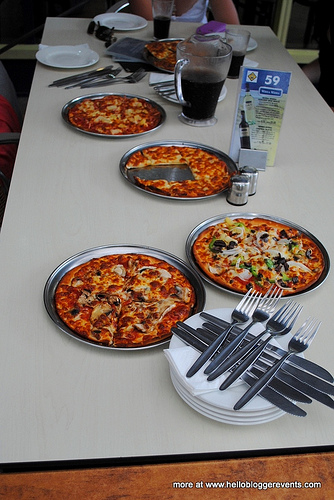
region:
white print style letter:
[172, 480, 179, 490]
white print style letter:
[179, 480, 185, 489]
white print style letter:
[185, 479, 187, 489]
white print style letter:
[187, 479, 193, 488]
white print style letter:
[194, 480, 199, 488]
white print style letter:
[199, 478, 203, 489]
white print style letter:
[204, 479, 211, 488]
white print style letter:
[208, 480, 218, 488]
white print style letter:
[218, 481, 224, 488]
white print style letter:
[225, 478, 230, 488]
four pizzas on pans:
[40, 89, 332, 353]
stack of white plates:
[167, 305, 309, 428]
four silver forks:
[184, 279, 324, 411]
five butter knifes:
[167, 309, 332, 422]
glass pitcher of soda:
[172, 32, 234, 127]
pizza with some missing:
[118, 138, 239, 204]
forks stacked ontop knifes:
[167, 285, 331, 421]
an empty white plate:
[32, 43, 103, 70]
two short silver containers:
[224, 161, 262, 207]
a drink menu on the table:
[227, 60, 294, 173]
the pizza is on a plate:
[45, 241, 205, 352]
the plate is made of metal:
[47, 239, 203, 356]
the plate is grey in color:
[38, 243, 206, 358]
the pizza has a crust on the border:
[62, 253, 192, 343]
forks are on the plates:
[191, 287, 316, 410]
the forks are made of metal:
[187, 289, 318, 407]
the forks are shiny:
[191, 286, 316, 414]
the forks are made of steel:
[189, 286, 321, 409]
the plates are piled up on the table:
[167, 304, 307, 426]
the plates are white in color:
[167, 306, 308, 429]